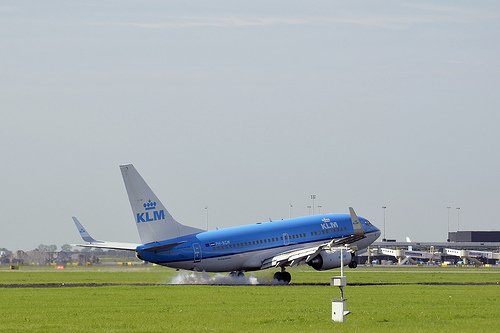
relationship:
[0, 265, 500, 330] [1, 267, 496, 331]
grass on field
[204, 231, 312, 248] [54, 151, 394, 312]
windows on airplane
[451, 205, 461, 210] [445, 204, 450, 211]
light next light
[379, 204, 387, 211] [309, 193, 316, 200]
light next light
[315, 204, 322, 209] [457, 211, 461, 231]
light next pole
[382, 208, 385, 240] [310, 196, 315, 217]
pole next pole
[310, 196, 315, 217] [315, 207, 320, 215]
pole next pole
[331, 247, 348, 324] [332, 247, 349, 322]
light on white box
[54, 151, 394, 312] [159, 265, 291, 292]
airplane has smoke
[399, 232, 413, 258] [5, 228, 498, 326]
lamp in airport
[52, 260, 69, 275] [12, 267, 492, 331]
red sign on ground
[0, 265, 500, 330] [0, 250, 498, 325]
grass around airport runway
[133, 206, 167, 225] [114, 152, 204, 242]
letters on airplane tail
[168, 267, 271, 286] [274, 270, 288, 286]
smoke around tires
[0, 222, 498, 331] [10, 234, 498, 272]
airport on distance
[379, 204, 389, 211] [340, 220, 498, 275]
light in terminal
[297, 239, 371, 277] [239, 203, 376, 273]
jet engine under wing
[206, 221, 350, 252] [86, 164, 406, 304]
windows in airplane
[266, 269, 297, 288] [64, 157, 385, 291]
tires on airplane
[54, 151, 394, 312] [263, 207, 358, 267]
airplane has right wing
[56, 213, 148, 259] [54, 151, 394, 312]
wing of airplane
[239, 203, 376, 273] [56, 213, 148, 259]
wing of wing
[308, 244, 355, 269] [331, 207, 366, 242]
jet engine under wing